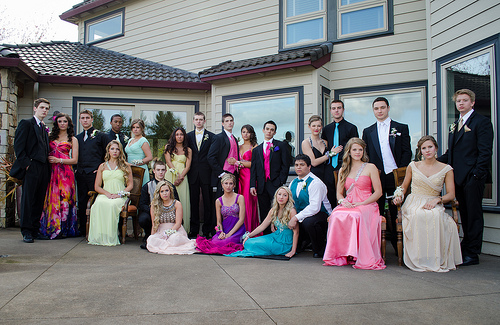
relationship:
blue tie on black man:
[323, 114, 353, 172] [104, 114, 132, 244]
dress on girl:
[226, 204, 296, 259] [239, 182, 301, 261]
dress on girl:
[206, 176, 253, 256] [202, 174, 246, 259]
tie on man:
[188, 126, 206, 136] [12, 96, 53, 241]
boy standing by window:
[440, 84, 492, 265] [434, 40, 495, 210]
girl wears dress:
[322, 129, 393, 271] [323, 171, 387, 267]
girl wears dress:
[222, 185, 299, 259] [403, 162, 461, 275]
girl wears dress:
[86, 139, 134, 246] [327, 174, 388, 271]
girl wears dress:
[390, 135, 463, 273] [237, 219, 297, 264]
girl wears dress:
[320, 137, 386, 271] [199, 194, 244, 244]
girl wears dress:
[161, 127, 193, 235] [145, 205, 201, 259]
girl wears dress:
[320, 137, 386, 271] [407, 163, 462, 273]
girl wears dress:
[390, 135, 463, 273] [325, 169, 384, 259]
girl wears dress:
[86, 139, 134, 246] [247, 217, 302, 252]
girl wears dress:
[43, 114, 77, 234] [203, 200, 248, 248]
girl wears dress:
[232, 122, 264, 224] [88, 170, 127, 249]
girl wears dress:
[36, 113, 81, 241] [400, 159, 470, 273]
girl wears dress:
[89, 131, 141, 246] [400, 159, 470, 273]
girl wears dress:
[144, 180, 200, 256] [90, 165, 134, 253]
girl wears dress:
[194, 167, 255, 252] [150, 199, 192, 251]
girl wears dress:
[222, 185, 299, 259] [207, 196, 253, 255]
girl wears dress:
[319, 133, 386, 275] [245, 207, 295, 260]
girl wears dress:
[390, 135, 463, 273] [326, 170, 386, 264]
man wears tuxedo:
[362, 95, 414, 215] [362, 119, 409, 243]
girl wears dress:
[194, 172, 247, 257] [194, 190, 245, 256]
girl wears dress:
[86, 139, 134, 246] [93, 160, 128, 254]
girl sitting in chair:
[86, 139, 134, 246] [85, 162, 150, 242]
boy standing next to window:
[431, 88, 494, 268] [438, 40, 498, 208]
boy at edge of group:
[431, 88, 494, 268] [15, 90, 493, 270]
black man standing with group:
[105, 107, 125, 139] [15, 90, 493, 270]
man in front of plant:
[6, 94, 61, 236] [151, 108, 184, 161]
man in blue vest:
[184, 108, 222, 225] [289, 175, 314, 213]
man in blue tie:
[184, 108, 222, 225] [297, 178, 304, 181]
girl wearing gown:
[390, 135, 463, 273] [401, 160, 462, 275]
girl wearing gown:
[320, 137, 386, 271] [325, 166, 383, 272]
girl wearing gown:
[222, 185, 299, 259] [224, 202, 292, 260]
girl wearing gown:
[144, 180, 200, 256] [148, 201, 195, 258]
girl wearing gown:
[86, 139, 134, 246] [84, 160, 128, 250]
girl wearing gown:
[319, 133, 386, 275] [319, 170, 387, 273]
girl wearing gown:
[390, 135, 463, 273] [406, 160, 470, 270]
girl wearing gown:
[222, 185, 299, 259] [247, 210, 297, 256]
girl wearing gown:
[194, 172, 247, 257] [214, 194, 244, 256]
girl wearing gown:
[147, 177, 192, 257] [149, 201, 193, 251]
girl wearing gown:
[82, 135, 138, 250] [93, 162, 126, 242]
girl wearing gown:
[44, 111, 84, 240] [45, 137, 81, 236]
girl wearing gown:
[122, 117, 152, 185] [127, 136, 153, 184]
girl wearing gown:
[165, 129, 195, 222] [164, 150, 192, 215]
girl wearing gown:
[227, 124, 263, 239] [232, 144, 259, 218]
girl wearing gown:
[300, 115, 343, 252] [305, 136, 331, 195]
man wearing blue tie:
[323, 95, 360, 174] [329, 123, 340, 169]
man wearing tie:
[438, 87, 497, 273] [458, 113, 468, 133]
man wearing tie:
[357, 97, 411, 207] [378, 119, 388, 147]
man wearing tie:
[285, 150, 328, 243] [294, 177, 306, 187]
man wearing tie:
[252, 122, 291, 202] [265, 140, 271, 178]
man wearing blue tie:
[213, 114, 244, 190] [297, 178, 304, 182]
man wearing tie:
[184, 108, 222, 225] [191, 126, 208, 141]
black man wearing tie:
[104, 114, 132, 244] [112, 130, 125, 145]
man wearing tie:
[69, 103, 109, 199] [80, 128, 92, 142]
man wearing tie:
[11, 92, 59, 238] [35, 119, 51, 135]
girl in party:
[222, 185, 299, 259] [8, 89, 494, 273]